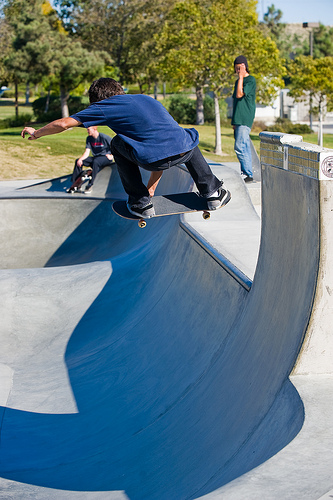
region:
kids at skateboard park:
[21, 76, 330, 272]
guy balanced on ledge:
[24, 71, 230, 234]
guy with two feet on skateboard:
[54, 77, 235, 235]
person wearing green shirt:
[221, 45, 267, 140]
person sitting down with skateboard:
[62, 121, 128, 202]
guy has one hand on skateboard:
[66, 82, 214, 224]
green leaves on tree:
[186, 20, 252, 145]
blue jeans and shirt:
[67, 80, 221, 220]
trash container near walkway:
[283, 99, 307, 126]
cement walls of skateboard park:
[33, 200, 231, 499]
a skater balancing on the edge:
[11, 64, 238, 245]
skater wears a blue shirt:
[13, 71, 220, 183]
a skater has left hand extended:
[10, 70, 171, 157]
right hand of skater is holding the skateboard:
[106, 135, 234, 226]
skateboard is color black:
[102, 175, 239, 234]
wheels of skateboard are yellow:
[133, 208, 212, 229]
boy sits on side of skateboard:
[58, 123, 116, 201]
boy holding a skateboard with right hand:
[220, 49, 268, 187]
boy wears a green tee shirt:
[218, 56, 264, 183]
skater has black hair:
[7, 61, 172, 149]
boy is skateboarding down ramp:
[19, 76, 230, 227]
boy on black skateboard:
[111, 188, 232, 228]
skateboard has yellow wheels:
[137, 211, 210, 227]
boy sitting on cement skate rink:
[65, 125, 113, 193]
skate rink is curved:
[0, 131, 332, 499]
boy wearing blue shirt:
[69, 93, 199, 164]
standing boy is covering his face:
[233, 54, 257, 181]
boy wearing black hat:
[233, 54, 248, 69]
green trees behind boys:
[0, 0, 332, 154]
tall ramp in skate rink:
[98, 130, 332, 499]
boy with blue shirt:
[40, 91, 231, 226]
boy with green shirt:
[219, 52, 276, 186]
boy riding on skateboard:
[23, 88, 240, 228]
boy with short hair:
[66, 70, 232, 233]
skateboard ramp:
[7, 225, 323, 437]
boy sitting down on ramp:
[59, 116, 116, 195]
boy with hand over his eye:
[215, 49, 284, 175]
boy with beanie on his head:
[217, 51, 271, 181]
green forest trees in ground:
[2, 1, 330, 73]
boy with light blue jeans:
[217, 55, 283, 198]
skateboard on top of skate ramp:
[99, 186, 240, 237]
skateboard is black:
[105, 176, 261, 237]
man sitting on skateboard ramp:
[71, 123, 123, 212]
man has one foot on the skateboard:
[22, 142, 120, 206]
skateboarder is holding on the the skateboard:
[107, 151, 197, 216]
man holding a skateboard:
[217, 120, 276, 193]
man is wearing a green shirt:
[224, 71, 273, 129]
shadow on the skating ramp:
[6, 167, 279, 498]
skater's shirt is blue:
[88, 98, 229, 199]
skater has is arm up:
[33, 85, 134, 162]